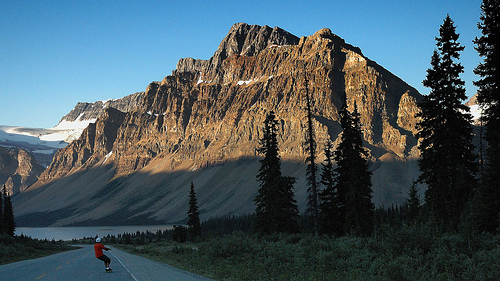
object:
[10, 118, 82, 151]
snow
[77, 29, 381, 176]
mountains